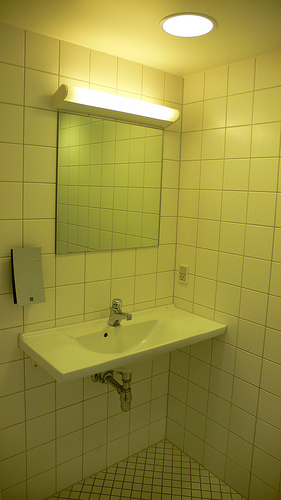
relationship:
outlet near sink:
[176, 263, 188, 284] [18, 303, 227, 385]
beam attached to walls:
[64, 79, 178, 123] [1, 18, 178, 500]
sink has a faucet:
[18, 303, 227, 385] [107, 299, 132, 327]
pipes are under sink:
[91, 366, 134, 412] [18, 303, 227, 385]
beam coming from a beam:
[64, 69, 178, 123] [64, 79, 178, 123]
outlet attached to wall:
[176, 263, 188, 284] [167, 51, 279, 498]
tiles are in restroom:
[38, 438, 253, 500] [0, 0, 280, 499]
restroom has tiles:
[0, 0, 280, 499] [38, 438, 253, 500]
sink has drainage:
[18, 303, 227, 385] [91, 366, 134, 412]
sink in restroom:
[18, 303, 227, 385] [0, 0, 280, 499]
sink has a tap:
[18, 303, 227, 385] [112, 299, 122, 306]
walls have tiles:
[1, 18, 281, 500] [0, 21, 280, 499]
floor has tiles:
[35, 438, 251, 500] [38, 438, 253, 500]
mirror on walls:
[55, 112, 164, 255] [1, 18, 178, 500]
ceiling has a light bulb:
[0, 0, 280, 78] [182, 17, 195, 28]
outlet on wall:
[176, 263, 188, 284] [167, 51, 279, 498]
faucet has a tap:
[107, 299, 132, 327] [112, 299, 122, 306]